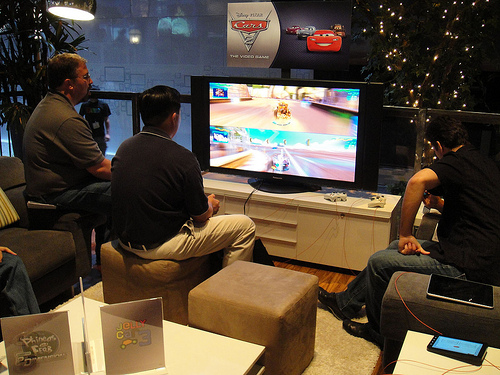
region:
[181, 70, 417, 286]
large television on a white stand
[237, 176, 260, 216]
black cord running down the stand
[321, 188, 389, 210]
two game controllers on the stand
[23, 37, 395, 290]
two people playing video games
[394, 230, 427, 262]
hand on the thigh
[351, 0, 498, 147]
white lights on a tree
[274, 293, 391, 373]
plush rug on the floor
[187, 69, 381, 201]
television is turned on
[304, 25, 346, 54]
a car with a face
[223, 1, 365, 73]
advertisement for Disney Pixar's Cars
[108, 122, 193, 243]
the shirt is black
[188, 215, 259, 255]
the pants are brown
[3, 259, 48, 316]
the jeans are blue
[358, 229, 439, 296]
the jeans is blue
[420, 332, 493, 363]
the phone is on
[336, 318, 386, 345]
the shoes are black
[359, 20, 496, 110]
lights are on the tree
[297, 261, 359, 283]
the fllor is wooden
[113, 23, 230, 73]
the wall is tiled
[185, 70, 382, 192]
it is a television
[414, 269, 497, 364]
it is tablet personal computer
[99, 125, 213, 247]
man wearing black shirt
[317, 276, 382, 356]
man wearing shoe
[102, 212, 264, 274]
man wearing white color pant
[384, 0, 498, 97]
it is a plant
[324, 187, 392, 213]
video game player key board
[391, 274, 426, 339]
it is a cable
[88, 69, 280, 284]
man sitting on bench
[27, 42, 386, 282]
men playing video games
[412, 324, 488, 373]
tablet on the counter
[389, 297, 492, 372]
red cables connected to tablet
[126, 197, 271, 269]
man wearing beige khakis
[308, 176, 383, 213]
video game controllers on the table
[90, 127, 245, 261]
man is wearing blue shirt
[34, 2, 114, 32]
light shining above the man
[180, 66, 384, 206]
a large flat screen tv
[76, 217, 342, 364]
two tan cushioned stools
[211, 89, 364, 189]
a game scene on the tv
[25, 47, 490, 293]
three guys watching tv screen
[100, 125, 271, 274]
a black shirt and tan pants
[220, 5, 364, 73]
an advertizement for Cars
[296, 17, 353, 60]
a red car with a smile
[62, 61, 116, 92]
glasses on man's face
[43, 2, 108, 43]
a light above man's head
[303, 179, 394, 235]
two white controlers by tv